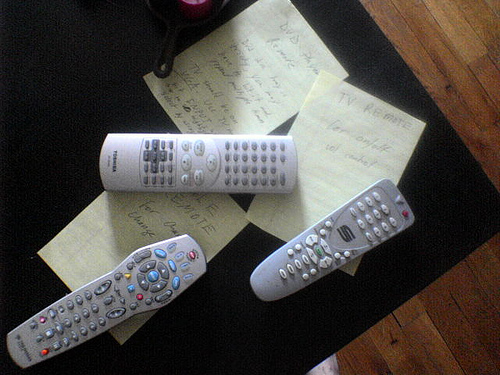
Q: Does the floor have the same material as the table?
A: Yes, both the floor and the table are made of wood.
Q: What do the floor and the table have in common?
A: The material, both the floor and the table are wooden.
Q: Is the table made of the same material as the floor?
A: Yes, both the table and the floor are made of wood.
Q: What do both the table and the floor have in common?
A: The material, both the table and the floor are wooden.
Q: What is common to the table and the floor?
A: The material, both the table and the floor are wooden.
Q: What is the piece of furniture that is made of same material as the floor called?
A: The piece of furniture is a table.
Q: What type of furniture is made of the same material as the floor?
A: The table is made of the same material as the floor.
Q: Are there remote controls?
A: Yes, there is a remote control.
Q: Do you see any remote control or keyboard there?
A: Yes, there is a remote control.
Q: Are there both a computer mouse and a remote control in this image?
A: No, there is a remote control but no computer mice.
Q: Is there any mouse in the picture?
A: No, there are no computer mice.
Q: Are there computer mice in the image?
A: No, there are no computer mice.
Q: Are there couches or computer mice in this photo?
A: No, there are no computer mice or couches.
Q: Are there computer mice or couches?
A: No, there are no computer mice or couches.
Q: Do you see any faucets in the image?
A: No, there are no faucets.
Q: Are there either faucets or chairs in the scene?
A: No, there are no faucets or chairs.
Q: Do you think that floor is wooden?
A: Yes, the floor is wooden.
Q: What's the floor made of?
A: The floor is made of wood.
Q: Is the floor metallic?
A: No, the floor is wooden.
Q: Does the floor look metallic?
A: No, the floor is wooden.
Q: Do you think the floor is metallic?
A: No, the floor is wooden.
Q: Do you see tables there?
A: Yes, there is a table.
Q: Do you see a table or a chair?
A: Yes, there is a table.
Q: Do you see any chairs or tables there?
A: Yes, there is a table.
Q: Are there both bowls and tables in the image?
A: No, there is a table but no bowls.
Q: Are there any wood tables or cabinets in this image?
A: Yes, there is a wood table.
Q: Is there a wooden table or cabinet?
A: Yes, there is a wood table.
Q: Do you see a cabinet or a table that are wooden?
A: Yes, the table is wooden.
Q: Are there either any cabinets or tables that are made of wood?
A: Yes, the table is made of wood.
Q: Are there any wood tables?
A: Yes, there is a table that is made of wood.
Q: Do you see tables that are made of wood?
A: Yes, there is a table that is made of wood.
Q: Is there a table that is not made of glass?
A: Yes, there is a table that is made of wood.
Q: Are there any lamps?
A: No, there are no lamps.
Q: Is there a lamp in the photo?
A: No, there are no lamps.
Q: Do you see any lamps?
A: No, there are no lamps.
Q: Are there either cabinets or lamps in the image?
A: No, there are no lamps or cabinets.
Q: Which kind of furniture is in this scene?
A: The furniture is a table.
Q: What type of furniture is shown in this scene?
A: The furniture is a table.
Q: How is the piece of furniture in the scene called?
A: The piece of furniture is a table.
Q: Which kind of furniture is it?
A: The piece of furniture is a table.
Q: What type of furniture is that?
A: This is a table.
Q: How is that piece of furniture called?
A: This is a table.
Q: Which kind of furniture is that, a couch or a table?
A: This is a table.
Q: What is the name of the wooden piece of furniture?
A: The piece of furniture is a table.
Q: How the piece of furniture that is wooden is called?
A: The piece of furniture is a table.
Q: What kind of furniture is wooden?
A: The furniture is a table.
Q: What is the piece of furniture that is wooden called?
A: The piece of furniture is a table.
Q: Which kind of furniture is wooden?
A: The furniture is a table.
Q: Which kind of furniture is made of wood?
A: The furniture is a table.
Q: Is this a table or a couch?
A: This is a table.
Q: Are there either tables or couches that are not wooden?
A: No, there is a table but it is wooden.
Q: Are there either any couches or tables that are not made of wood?
A: No, there is a table but it is made of wood.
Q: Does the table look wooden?
A: Yes, the table is wooden.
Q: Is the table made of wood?
A: Yes, the table is made of wood.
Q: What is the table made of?
A: The table is made of wood.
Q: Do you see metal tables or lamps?
A: No, there is a table but it is wooden.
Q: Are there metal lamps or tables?
A: No, there is a table but it is wooden.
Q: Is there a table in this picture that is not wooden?
A: No, there is a table but it is wooden.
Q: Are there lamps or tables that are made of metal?
A: No, there is a table but it is made of wood.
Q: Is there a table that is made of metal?
A: No, there is a table but it is made of wood.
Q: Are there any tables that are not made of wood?
A: No, there is a table but it is made of wood.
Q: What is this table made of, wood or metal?
A: The table is made of wood.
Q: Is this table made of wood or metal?
A: The table is made of wood.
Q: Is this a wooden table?
A: Yes, this is a wooden table.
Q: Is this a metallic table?
A: No, this is a wooden table.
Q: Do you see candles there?
A: No, there are no candles.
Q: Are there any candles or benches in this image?
A: No, there are no candles or benches.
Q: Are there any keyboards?
A: Yes, there is a keyboard.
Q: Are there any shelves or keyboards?
A: Yes, there is a keyboard.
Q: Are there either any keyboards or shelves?
A: Yes, there is a keyboard.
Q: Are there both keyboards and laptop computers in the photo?
A: No, there is a keyboard but no laptops.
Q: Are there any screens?
A: No, there are no screens.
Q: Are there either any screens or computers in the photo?
A: No, there are no screens or computers.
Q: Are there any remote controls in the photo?
A: Yes, there is a remote control.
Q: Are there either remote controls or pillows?
A: Yes, there is a remote control.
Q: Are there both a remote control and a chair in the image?
A: No, there is a remote control but no chairs.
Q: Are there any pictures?
A: No, there are no pictures.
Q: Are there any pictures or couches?
A: No, there are no pictures or couches.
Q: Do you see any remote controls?
A: Yes, there is a remote control.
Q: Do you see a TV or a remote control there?
A: Yes, there is a remote control.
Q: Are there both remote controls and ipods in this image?
A: No, there is a remote control but no ipods.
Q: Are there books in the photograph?
A: No, there are no books.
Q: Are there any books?
A: No, there are no books.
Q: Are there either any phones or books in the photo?
A: No, there are no books or phones.